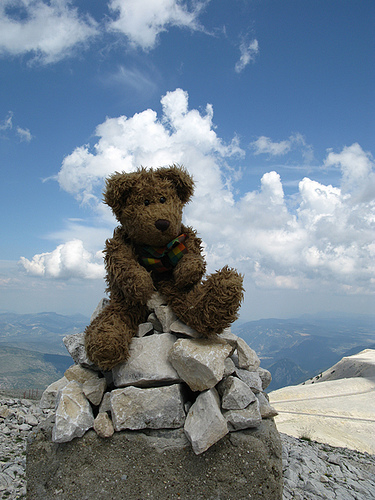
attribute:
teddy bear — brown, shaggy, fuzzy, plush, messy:
[83, 162, 244, 373]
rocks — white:
[38, 290, 279, 460]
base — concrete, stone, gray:
[26, 404, 282, 498]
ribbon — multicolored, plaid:
[131, 233, 189, 273]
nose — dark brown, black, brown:
[152, 217, 174, 235]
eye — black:
[142, 194, 150, 207]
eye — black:
[158, 194, 166, 206]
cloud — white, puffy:
[17, 84, 373, 299]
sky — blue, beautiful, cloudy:
[1, 0, 374, 318]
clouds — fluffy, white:
[3, 1, 374, 296]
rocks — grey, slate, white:
[1, 395, 374, 499]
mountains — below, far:
[1, 311, 374, 404]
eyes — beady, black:
[140, 192, 166, 209]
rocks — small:
[1, 395, 56, 499]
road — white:
[2, 337, 374, 360]